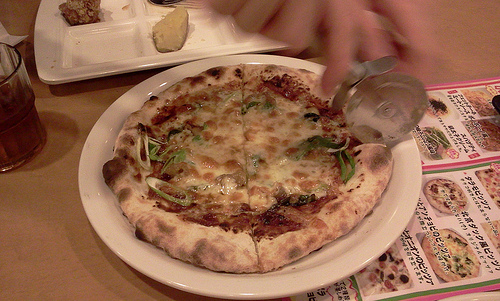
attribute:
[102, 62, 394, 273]
pizza — big, small, burnt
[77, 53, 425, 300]
plate — white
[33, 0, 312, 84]
tray — white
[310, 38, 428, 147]
pizza cutter — silver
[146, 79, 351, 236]
cheese — melted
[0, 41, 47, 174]
cup — half-full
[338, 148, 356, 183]
vegetable — green